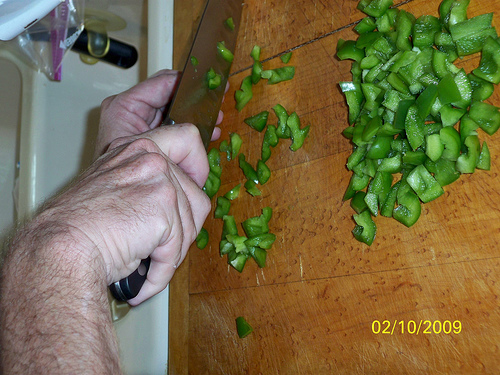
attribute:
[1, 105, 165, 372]
forearms — hairy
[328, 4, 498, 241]
green peppers — chopped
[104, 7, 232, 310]
knife — big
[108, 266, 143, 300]
handle — black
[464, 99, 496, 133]
pepper — green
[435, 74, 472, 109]
pepper — green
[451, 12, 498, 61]
pepper — green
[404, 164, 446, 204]
pepper — green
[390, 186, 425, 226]
pepper — green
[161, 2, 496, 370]
cutting board — light brown, wood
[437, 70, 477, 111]
pepper — green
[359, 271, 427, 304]
marks — striation, cutting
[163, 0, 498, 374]
board — wooden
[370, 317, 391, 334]
02 — yellow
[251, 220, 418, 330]
cutting board — wooden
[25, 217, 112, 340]
arm — hairy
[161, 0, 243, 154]
knife — large, metal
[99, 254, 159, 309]
handle — black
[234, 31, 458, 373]
board — brown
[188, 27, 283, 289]
peppers — green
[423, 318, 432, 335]
2 — yellow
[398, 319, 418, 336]
10 — yellow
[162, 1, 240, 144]
knife — black, silver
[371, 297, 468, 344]
date — 02/10/2009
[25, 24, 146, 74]
object — black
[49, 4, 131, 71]
holder — plastic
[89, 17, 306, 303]
knife — big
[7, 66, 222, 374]
male — white, cutting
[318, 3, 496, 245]
peppers — green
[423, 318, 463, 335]
year — 2009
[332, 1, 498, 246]
green pepper — reflection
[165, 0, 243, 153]
blade — silver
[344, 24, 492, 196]
peppers — green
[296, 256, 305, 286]
scratches — white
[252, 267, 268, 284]
scratches — white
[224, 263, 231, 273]
scratches — white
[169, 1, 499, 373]
table — wooden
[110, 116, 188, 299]
handle — black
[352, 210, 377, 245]
pepper — chopped, diced, green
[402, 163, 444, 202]
pepper — chopped, diced, green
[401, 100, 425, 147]
pepper — chopped, diced, green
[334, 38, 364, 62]
pepper — chopped, diced, green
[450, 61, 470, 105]
pepper — chopped, diced, green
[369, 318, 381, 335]
number — yellow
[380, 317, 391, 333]
number — yellow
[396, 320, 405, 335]
number — yellow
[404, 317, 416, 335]
number — yellow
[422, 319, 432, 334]
number — yellow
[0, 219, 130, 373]
arm — hairy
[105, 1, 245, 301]
knife — metallic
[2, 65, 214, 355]
male — white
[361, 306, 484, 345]
print — yellow